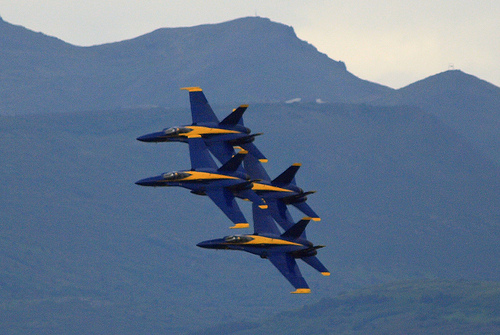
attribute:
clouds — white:
[89, 13, 120, 23]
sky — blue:
[0, 0, 497, 334]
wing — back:
[293, 213, 336, 280]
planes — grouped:
[135, 73, 338, 302]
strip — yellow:
[244, 232, 294, 249]